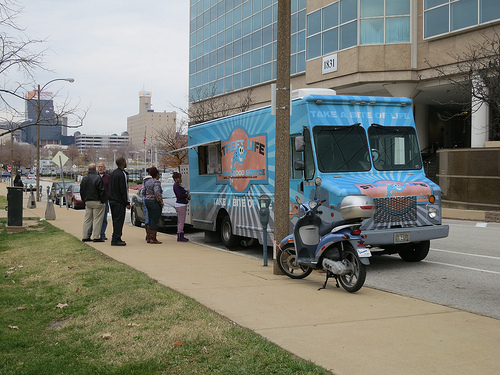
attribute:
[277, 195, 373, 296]
motor scooter — blue, parked, blie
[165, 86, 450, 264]
food truck — blue, orange, white, parked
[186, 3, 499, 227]
building — tall, multi story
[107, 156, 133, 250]
man — standing, waiting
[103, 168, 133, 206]
jacket — black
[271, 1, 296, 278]
street light — tall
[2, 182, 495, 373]
sidewalk — long, paved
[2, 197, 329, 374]
grass — dark green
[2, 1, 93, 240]
tree — tall, bare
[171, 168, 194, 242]
person — standing, waiting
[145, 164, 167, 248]
woman — waiting, standing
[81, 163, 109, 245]
man — talking, standing, waiting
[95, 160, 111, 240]
man — talking, standing, waiting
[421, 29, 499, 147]
tree — bare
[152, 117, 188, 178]
tree — bare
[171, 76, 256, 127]
tree — bare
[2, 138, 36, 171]
tree — bare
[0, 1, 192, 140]
sky — overcast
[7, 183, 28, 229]
trash bin — black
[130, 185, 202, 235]
car — parked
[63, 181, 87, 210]
car — parked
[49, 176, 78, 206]
car — parked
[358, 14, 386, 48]
window — green tinted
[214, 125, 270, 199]
sign — orange, advertising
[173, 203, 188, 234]
pants — purple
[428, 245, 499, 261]
line — white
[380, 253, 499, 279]
line — white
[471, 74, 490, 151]
pillar — white